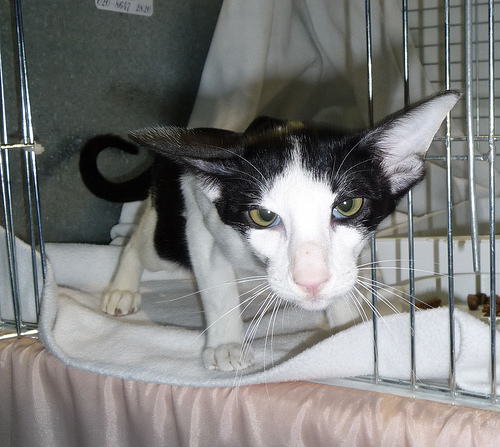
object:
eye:
[241, 197, 283, 231]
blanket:
[28, 220, 497, 419]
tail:
[69, 127, 156, 202]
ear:
[358, 65, 445, 205]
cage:
[2, 2, 498, 396]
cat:
[76, 96, 482, 372]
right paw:
[204, 341, 254, 373]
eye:
[329, 189, 365, 223]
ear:
[120, 117, 256, 178]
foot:
[101, 287, 146, 319]